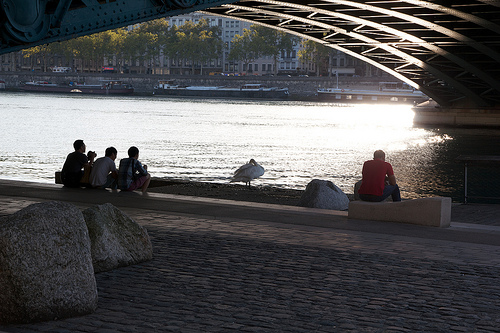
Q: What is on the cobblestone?
A: A large gray rock.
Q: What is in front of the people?
A: A wide river is in front of the people.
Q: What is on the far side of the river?
A: There are trees on the far side of the river.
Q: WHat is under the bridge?
A: A metal grid.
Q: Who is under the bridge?
A: There are four people under the bridge.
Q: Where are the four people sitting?
A: The four people are sitting under the bridge.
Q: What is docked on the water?
A: Three large boats are docked on the water.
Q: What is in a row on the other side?
A: There are a row of green trees.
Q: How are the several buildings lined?
A: THe several buildings are in a row.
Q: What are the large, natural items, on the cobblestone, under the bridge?
A: Rocks.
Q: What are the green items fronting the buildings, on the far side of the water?
A: Trees.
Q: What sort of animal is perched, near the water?
A: A bird.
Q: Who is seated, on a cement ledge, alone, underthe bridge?
A: A person in a red shirt.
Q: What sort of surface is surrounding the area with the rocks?
A: Cobblestone.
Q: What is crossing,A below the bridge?
A: A river.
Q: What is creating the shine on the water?
A: Sunlight.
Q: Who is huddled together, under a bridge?
A: Three guys.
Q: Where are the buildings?
A: On the far side of the river.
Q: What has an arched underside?
A: A bridge,over a river.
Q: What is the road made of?
A: Cobblestone.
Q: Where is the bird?
A: By the river.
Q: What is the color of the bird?
A: White.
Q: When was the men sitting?
A: Daytime.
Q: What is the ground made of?
A: Stones and bricks.